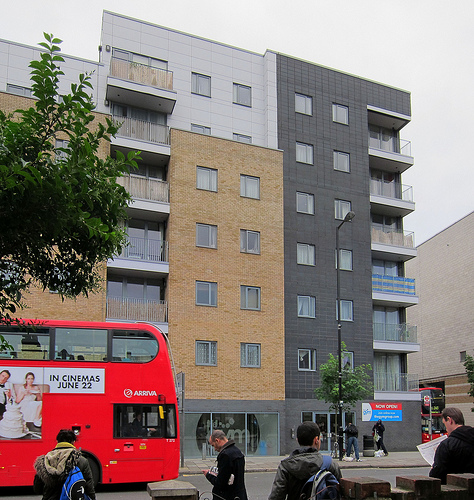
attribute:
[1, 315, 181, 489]
bus — double decker, red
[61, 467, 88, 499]
backpack — blue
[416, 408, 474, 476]
man — reading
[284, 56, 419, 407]
apartment building — grey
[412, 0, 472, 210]
sky — clear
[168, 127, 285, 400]
brown building — tan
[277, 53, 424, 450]
building — grey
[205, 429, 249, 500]
man — reading, balding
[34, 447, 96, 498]
jacket — hooded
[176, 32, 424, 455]
building — tiled, apartment complex, tall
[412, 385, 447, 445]
bus — double decker, red